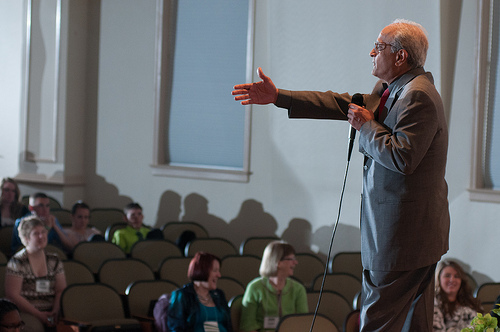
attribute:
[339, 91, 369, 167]
mic — black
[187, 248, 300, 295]
women — laughing, sitting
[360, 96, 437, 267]
coat — gray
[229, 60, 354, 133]
arm — extended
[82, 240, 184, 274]
seats — empty